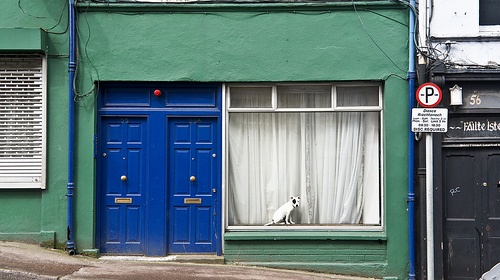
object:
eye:
[291, 197, 297, 204]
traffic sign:
[415, 81, 442, 108]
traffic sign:
[408, 107, 449, 134]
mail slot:
[112, 196, 132, 205]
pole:
[63, 0, 78, 255]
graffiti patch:
[448, 184, 462, 196]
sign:
[446, 118, 485, 138]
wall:
[1, 1, 414, 277]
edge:
[377, 84, 384, 230]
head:
[287, 194, 302, 209]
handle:
[189, 173, 196, 182]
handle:
[360, 150, 374, 172]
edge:
[340, 227, 373, 245]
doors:
[109, 83, 219, 246]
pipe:
[50, 5, 84, 250]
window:
[220, 117, 381, 234]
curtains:
[241, 128, 361, 215]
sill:
[233, 221, 388, 241]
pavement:
[90, 247, 295, 273]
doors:
[430, 90, 494, 277]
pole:
[405, 72, 445, 267]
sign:
[403, 64, 447, 130]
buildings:
[20, 0, 467, 275]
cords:
[410, 39, 448, 83]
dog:
[260, 186, 308, 231]